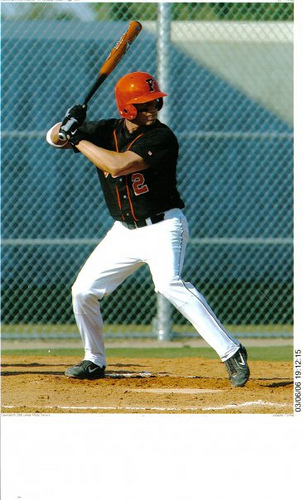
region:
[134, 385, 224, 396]
A base plate below the batter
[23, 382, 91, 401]
Dirt near the base plate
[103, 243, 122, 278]
The player's pants are white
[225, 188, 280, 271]
A fence behind the player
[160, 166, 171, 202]
Black fabric on the baseball jersey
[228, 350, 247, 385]
A black shoe on the left foot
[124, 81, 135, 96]
A red baseball helmet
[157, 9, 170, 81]
A silver pole behind the batter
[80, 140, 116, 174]
Left arm of the baseball player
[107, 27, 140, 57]
The top of the bat is red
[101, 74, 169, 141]
man wearing baseball helmet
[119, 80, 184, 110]
baseball helmet is orange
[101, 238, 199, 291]
man wearing white pants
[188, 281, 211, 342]
white pants with black stripe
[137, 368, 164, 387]
orange dirt with white stripes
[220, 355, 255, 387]
man wearing black shoes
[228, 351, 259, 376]
black shoes with white check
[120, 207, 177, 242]
man wearing black belt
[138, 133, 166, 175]
man wearing black jersey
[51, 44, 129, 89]
man holding wooden bat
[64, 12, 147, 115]
A brown and black baseball bat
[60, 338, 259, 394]
A pair of black and white Nike shoes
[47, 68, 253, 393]
A baseball player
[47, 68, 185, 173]
A baseball player wearing an orange helmet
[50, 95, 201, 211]
A baseball player wearing a black shirt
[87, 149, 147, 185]
A man's elbow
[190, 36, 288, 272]
A silver chain link fence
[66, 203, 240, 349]
A man wearing white pants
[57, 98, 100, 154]
A man wearing black gloves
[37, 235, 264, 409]
A man standing at home plate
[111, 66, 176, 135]
orange batting helmet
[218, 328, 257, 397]
Nike baseball shoes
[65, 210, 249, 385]
white baseball uniform pants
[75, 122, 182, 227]
a black and red baseball uniform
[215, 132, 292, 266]
chain link fencing around field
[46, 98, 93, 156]
batting gloves gripping a bat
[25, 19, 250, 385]
baseball player preparing to swing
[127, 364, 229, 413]
baseball clay with white lines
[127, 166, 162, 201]
number 2 jersey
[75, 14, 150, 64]
brown rounded end of baseball bat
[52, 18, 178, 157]
a man holding a bat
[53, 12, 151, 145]
a brown bat with a black handle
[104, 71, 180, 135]
a man wearing a orange helmet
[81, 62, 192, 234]
a man wearing a black shirt with orange stripe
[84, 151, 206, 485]
a man wearing white pants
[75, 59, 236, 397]
a man wearing a baseball uniform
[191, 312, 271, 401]
a man wearing black tennis shoes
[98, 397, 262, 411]
a white chalk line on a baseball field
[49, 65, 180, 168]
a man wearing black gloves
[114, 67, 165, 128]
a orange helmet with the letter F on it